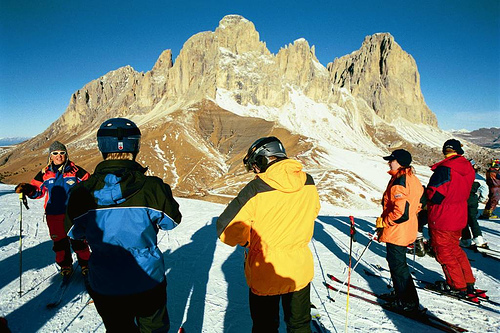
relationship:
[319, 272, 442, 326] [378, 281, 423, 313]
skis are on feet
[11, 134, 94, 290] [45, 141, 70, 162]
woman wearing sunglasses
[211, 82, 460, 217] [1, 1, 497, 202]
snow on mountain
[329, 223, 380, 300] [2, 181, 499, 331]
ski pole on snow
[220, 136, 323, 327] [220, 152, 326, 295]
skier wearing jacket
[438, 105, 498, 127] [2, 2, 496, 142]
clouds are in sky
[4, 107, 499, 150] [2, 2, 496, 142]
clouds are in sky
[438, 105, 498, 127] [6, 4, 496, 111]
clouds are in sky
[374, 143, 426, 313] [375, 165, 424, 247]
skier wearing coat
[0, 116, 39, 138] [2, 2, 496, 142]
clouds are in sky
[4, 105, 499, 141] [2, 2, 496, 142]
clouds are in sky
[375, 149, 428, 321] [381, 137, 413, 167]
skier has hat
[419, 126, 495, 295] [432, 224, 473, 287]
man has pants